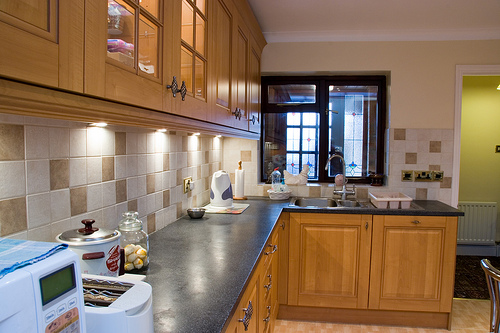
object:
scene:
[3, 3, 495, 333]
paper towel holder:
[229, 158, 250, 200]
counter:
[174, 222, 225, 329]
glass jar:
[119, 209, 151, 272]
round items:
[127, 241, 146, 271]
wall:
[394, 49, 444, 130]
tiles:
[392, 128, 408, 143]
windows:
[264, 77, 328, 186]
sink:
[295, 195, 370, 210]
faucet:
[333, 176, 359, 202]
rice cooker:
[53, 219, 127, 278]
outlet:
[182, 177, 194, 194]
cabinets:
[1, 0, 86, 96]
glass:
[107, 3, 139, 64]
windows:
[180, 0, 214, 97]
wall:
[9, 124, 160, 201]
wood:
[4, 3, 95, 74]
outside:
[333, 102, 363, 169]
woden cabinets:
[366, 214, 451, 323]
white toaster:
[71, 271, 160, 331]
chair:
[472, 256, 500, 332]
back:
[479, 258, 498, 333]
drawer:
[260, 225, 279, 272]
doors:
[373, 215, 453, 314]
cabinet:
[290, 215, 369, 311]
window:
[328, 86, 386, 187]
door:
[454, 69, 500, 251]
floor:
[460, 261, 486, 328]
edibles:
[129, 245, 147, 266]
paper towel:
[234, 170, 245, 198]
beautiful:
[394, 132, 439, 159]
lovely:
[106, 34, 138, 54]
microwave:
[1, 237, 92, 331]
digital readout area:
[39, 268, 80, 306]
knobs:
[166, 75, 179, 98]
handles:
[237, 301, 254, 329]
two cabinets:
[85, 0, 215, 123]